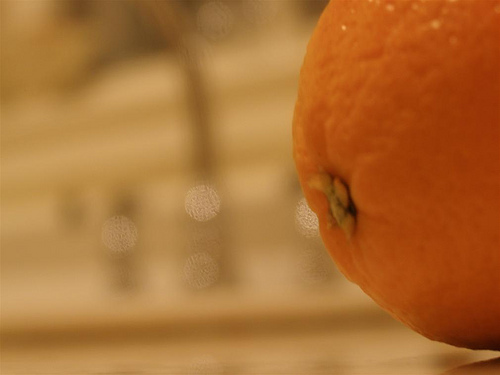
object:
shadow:
[437, 354, 500, 375]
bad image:
[0, 0, 500, 375]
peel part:
[429, 203, 487, 293]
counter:
[0, 297, 500, 375]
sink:
[0, 297, 382, 348]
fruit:
[288, 0, 500, 354]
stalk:
[323, 173, 356, 241]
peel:
[290, 0, 498, 352]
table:
[0, 328, 500, 375]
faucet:
[57, 19, 239, 301]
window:
[57, 0, 327, 52]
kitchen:
[0, 0, 500, 375]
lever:
[270, 174, 338, 293]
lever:
[48, 178, 150, 295]